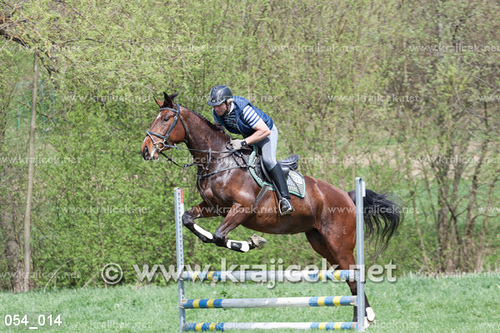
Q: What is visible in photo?
A: A horse.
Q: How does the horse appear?
A: Visible.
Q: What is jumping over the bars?
A: Visible horse.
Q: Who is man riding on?
A: Horse that is visible.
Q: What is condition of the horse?
A: Visible.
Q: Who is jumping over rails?
A: Visible horse.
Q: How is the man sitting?
A: Leaning forward.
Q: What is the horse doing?
A: Jumping.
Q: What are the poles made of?
A: Metal.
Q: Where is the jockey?
A: On horse.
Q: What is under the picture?
A: It's watermarked.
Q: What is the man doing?
A: Riding a red hours.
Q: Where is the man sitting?
A: Atop of horse.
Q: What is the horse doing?
A: Jumping with man.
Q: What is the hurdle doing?
A: Jumping.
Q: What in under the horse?
A: A hurdle.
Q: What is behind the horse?
A: Trees and bushes.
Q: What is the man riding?
A: A horse.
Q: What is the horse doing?
A: Jumping.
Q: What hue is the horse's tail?
A: Black.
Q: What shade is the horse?
A: Brown.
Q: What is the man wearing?
A: Black boots.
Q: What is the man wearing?
A: Helmet.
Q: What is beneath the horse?
A: Green grass.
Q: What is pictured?
A: A horse.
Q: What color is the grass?
A: Green.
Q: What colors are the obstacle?
A: Blue, white, and yellow.